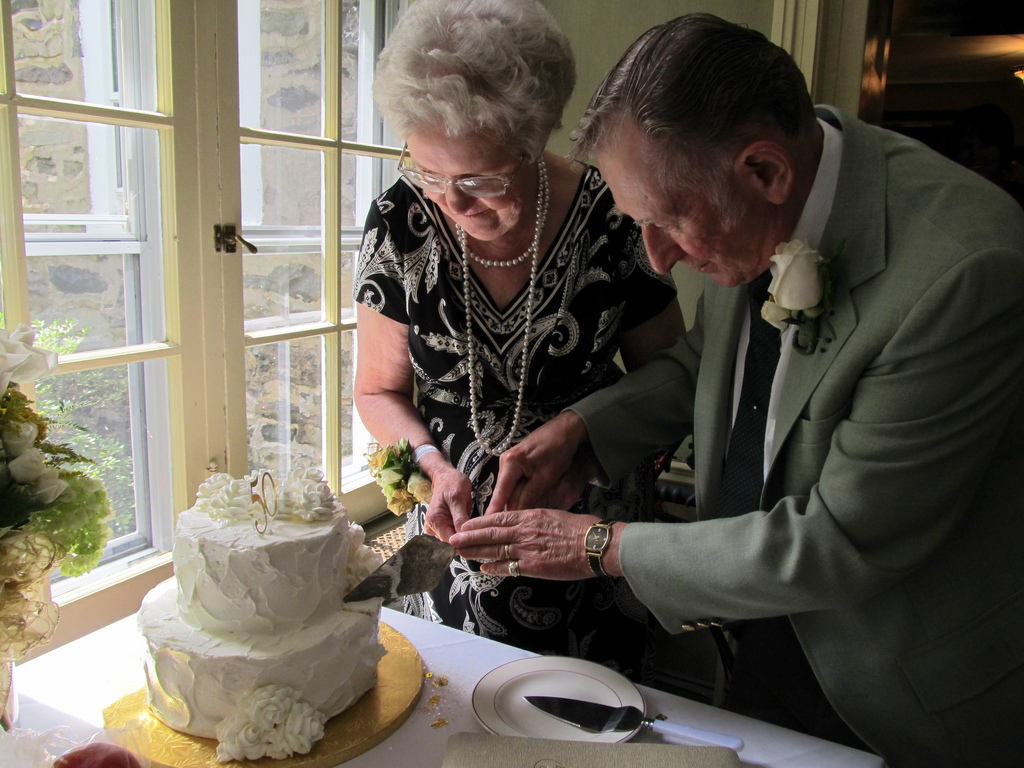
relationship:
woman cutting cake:
[353, 0, 684, 673] [140, 463, 387, 764]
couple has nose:
[351, 0, 1024, 768] [639, 227, 683, 279]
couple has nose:
[351, 0, 1024, 768] [427, 183, 471, 212]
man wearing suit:
[526, 30, 941, 633] [651, 257, 971, 647]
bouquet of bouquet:
[14, 378, 114, 655] [0, 323, 110, 726]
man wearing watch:
[451, 13, 1024, 767] [550, 484, 630, 588]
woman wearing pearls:
[372, 11, 681, 705] [407, 147, 576, 487]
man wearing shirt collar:
[451, 13, 1024, 767] [785, 108, 840, 377]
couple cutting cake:
[341, 7, 988, 755] [140, 463, 387, 764]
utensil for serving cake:
[335, 532, 459, 610] [140, 463, 387, 764]